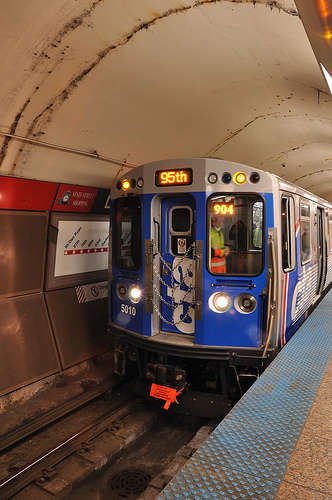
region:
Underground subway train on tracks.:
[71, 138, 331, 454]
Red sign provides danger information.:
[137, 363, 194, 411]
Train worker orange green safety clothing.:
[208, 208, 241, 283]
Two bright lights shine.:
[119, 273, 239, 305]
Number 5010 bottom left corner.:
[116, 296, 149, 330]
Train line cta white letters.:
[167, 251, 199, 336]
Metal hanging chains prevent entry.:
[153, 203, 204, 343]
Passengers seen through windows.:
[247, 194, 320, 258]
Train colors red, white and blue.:
[265, 192, 306, 349]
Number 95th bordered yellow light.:
[118, 166, 255, 189]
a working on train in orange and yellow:
[207, 217, 229, 273]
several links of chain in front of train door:
[144, 239, 197, 326]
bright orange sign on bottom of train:
[145, 372, 183, 413]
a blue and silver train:
[108, 159, 329, 418]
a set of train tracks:
[0, 380, 143, 499]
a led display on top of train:
[154, 168, 192, 187]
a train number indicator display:
[212, 200, 237, 215]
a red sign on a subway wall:
[0, 175, 99, 217]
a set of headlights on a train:
[126, 282, 229, 314]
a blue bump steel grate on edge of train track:
[155, 281, 330, 498]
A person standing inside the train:
[210, 217, 230, 274]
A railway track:
[57, 389, 123, 442]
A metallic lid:
[111, 460, 150, 496]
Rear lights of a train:
[116, 166, 250, 225]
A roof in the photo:
[121, 36, 240, 110]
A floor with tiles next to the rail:
[226, 402, 292, 461]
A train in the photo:
[98, 153, 325, 371]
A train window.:
[269, 191, 301, 277]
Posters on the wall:
[55, 216, 104, 275]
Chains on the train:
[150, 243, 200, 326]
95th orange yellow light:
[155, 164, 189, 188]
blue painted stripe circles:
[223, 407, 307, 474]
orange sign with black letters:
[146, 380, 184, 409]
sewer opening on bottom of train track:
[90, 443, 162, 496]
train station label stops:
[53, 215, 109, 278]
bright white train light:
[124, 282, 143, 306]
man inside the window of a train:
[204, 205, 260, 284]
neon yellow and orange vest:
[205, 224, 234, 274]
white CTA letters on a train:
[162, 250, 203, 343]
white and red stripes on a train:
[279, 271, 295, 350]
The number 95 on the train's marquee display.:
[159, 169, 176, 180]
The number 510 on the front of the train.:
[114, 300, 138, 316]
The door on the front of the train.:
[161, 198, 196, 332]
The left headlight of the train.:
[122, 283, 151, 304]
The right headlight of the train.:
[211, 292, 232, 317]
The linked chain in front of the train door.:
[150, 248, 192, 324]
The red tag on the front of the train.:
[144, 380, 178, 405]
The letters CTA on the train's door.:
[168, 251, 193, 333]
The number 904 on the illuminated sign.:
[213, 204, 231, 213]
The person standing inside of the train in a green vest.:
[211, 211, 236, 275]